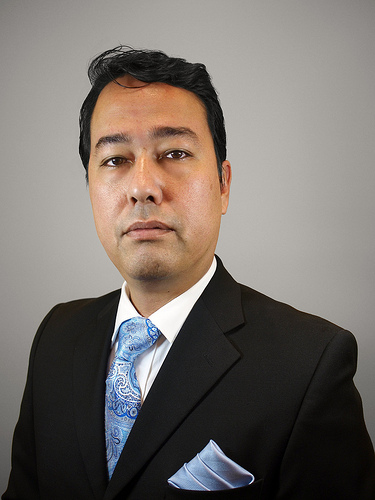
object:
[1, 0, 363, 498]
background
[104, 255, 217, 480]
shirt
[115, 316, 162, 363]
knot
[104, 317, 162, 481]
neck tie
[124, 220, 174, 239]
mouth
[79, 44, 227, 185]
hair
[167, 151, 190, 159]
eye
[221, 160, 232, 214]
ear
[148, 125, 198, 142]
eyebrow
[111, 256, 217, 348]
collar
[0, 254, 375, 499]
suit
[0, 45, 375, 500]
man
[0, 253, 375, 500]
jacket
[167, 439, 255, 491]
handkerchief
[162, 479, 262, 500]
pocket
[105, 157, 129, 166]
eyes